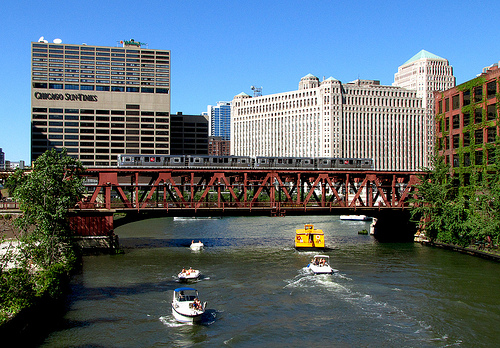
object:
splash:
[300, 268, 356, 298]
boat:
[307, 255, 334, 276]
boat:
[190, 240, 204, 251]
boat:
[171, 287, 208, 325]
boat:
[177, 265, 201, 284]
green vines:
[443, 160, 486, 210]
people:
[181, 266, 195, 277]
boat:
[295, 224, 325, 247]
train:
[112, 146, 383, 182]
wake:
[283, 263, 353, 295]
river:
[1, 211, 498, 346]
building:
[31, 36, 499, 167]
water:
[0, 217, 500, 346]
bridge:
[0, 168, 433, 255]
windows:
[234, 88, 424, 172]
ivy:
[411, 74, 499, 246]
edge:
[208, 167, 274, 171]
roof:
[165, 261, 211, 285]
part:
[310, 270, 320, 284]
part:
[269, 322, 351, 342]